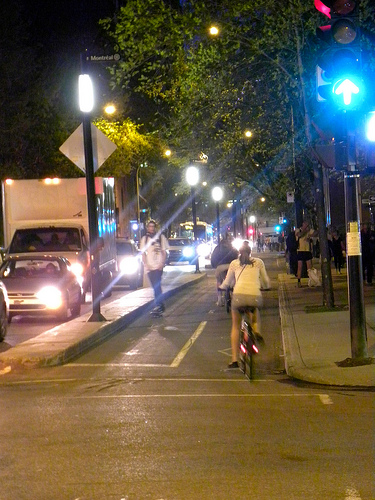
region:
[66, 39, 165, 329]
tall post with street sign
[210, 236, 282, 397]
woman riding a bicycle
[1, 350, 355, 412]
crosswalk in white paint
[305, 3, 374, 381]
traffic signal on black pole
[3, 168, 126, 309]
large white box truck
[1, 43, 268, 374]
series of street lights on concrete median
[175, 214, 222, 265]
white passenger bus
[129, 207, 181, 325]
man riding skateboard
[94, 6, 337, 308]
tall tree with small leaves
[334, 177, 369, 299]
paper sign taped on pole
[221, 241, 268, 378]
Woman on a bicycle.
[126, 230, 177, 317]
Man skateboarding in the street.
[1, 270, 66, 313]
Car with lights on.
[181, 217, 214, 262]
Bus driving down the street.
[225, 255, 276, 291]
Woman wearing a white shirt.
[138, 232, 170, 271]
Man in white shirt.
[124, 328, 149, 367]
Arrow painted on the road.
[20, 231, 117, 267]
White truck with its lights on.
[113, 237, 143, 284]
Car with lights on.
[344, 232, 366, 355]
Black telephone pole on sidewalk.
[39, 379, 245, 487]
this is a road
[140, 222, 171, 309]
this is a man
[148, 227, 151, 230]
the man has a light skin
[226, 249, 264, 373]
the lady is ridding a bicycle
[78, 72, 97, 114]
this is a lump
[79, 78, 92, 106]
the lump is lighting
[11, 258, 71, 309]
this is a car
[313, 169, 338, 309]
this is a pole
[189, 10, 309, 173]
this is a tree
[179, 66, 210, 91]
the tree has green leaves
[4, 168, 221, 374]
vehicles on the road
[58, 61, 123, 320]
street sign seen from behind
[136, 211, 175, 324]
person on a skateboard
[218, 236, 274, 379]
woman on bicycle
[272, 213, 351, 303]
people on sidewalk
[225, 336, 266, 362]
lights on the back of a bicycle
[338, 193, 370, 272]
sign attached to pole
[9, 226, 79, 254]
people in vehicle seen through windshield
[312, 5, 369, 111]
green arrow on traffic light is illuminated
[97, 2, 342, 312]
tall trees over sidewalk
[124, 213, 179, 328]
man walking on city street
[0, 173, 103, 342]
a car and truck traveling at night with lights on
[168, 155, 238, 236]
streetlights on at night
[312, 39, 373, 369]
pole with arrow light on corner of street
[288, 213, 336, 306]
man standing on street at night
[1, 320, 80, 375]
concrete curb on street corner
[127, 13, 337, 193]
a green tree along the sidewalk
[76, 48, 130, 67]
street sign at night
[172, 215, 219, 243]
transit bus on city street at night